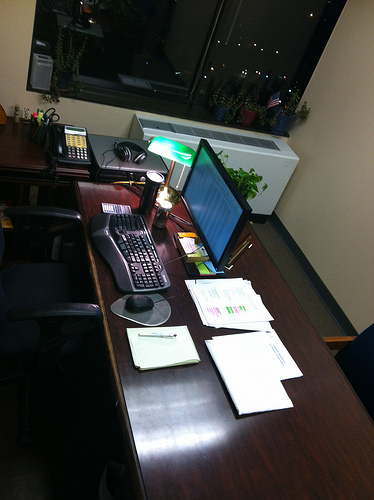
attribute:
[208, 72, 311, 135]
row — of plants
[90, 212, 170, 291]
keyboard — black, one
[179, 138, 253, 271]
monitor — flat screen, on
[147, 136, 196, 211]
desk lamp — small, green, turned on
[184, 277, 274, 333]
stack — of paper, of papers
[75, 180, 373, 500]
desk — brown, wooden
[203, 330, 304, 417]
stack — of paper, of papers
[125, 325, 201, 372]
stack — of paper, of papers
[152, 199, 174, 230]
can — of soda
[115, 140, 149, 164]
headphone — paired, black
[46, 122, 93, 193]
telephone — one, black, digital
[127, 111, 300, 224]
air conditioning — white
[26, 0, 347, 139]
window — big, large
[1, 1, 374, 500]
office — large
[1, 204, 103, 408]
computer chair — leather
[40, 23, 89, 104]
plant — potted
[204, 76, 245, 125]
plant — potted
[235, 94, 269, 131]
plant — potted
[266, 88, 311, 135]
plant — potted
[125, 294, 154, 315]
computer mouse — black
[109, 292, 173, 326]
mouse pad — gray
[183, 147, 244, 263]
screen — blue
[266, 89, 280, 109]
flag — american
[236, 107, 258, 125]
plant pot — red